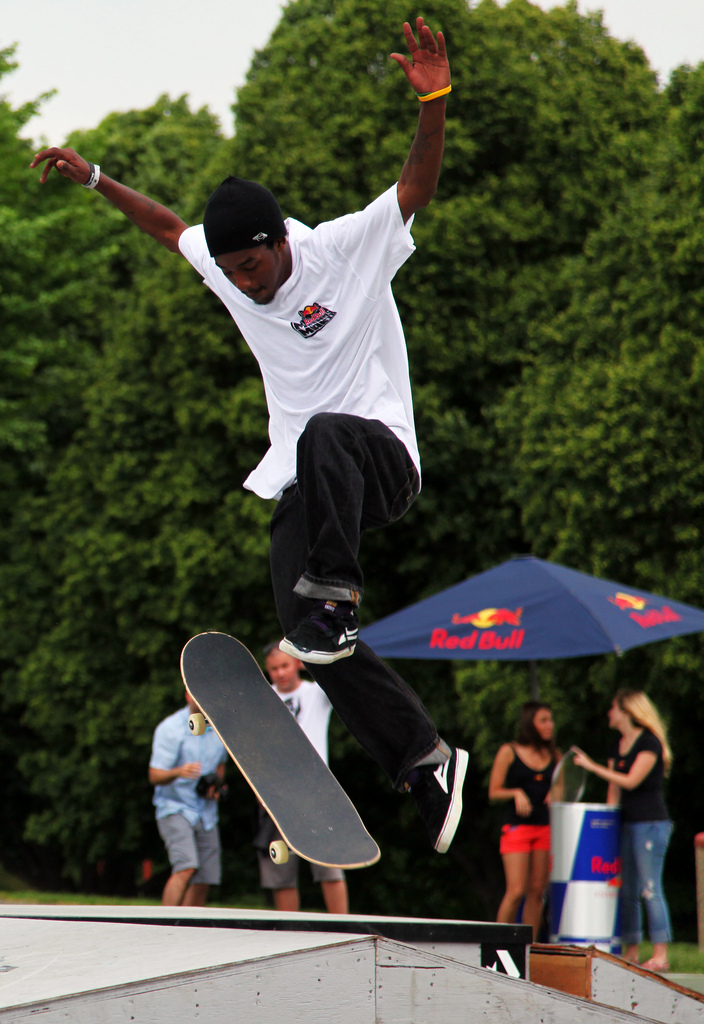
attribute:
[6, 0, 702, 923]
trees — green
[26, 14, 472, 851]
skater — jumping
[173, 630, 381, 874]
skateboard — black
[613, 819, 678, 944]
jeans — blue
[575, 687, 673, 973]
woman — blonde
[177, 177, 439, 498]
shirt — white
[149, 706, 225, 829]
shirt — blue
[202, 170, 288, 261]
hat — black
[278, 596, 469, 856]
shoes — black, white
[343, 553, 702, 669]
umbrella — blue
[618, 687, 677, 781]
hair — blonde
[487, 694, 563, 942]
woman — brunette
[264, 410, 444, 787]
jeans — black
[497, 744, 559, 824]
tank top — black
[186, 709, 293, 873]
wheels — white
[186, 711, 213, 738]
wheel — white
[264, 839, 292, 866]
wheel — white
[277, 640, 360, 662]
sole — white